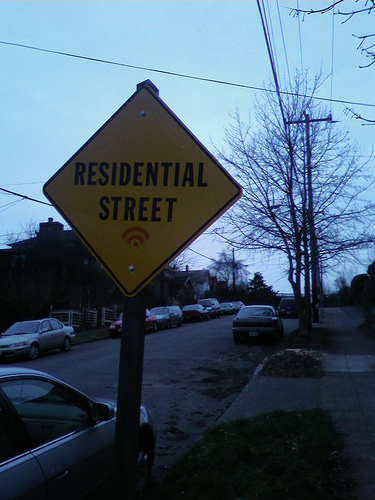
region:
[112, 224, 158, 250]
a few orange lines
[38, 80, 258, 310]
a bright yellow street sign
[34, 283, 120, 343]
a simple wood fence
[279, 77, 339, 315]
a wood telephone post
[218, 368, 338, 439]
a concrete drive way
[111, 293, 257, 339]
a row of parked cars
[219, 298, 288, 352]
a light colored sedan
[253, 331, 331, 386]
a patch of grass covered in leaves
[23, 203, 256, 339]
a row of houses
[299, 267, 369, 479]
a long cement sidewalk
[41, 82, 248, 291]
a yellow street sign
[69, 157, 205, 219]
black printed words RESIDENTIAL STREET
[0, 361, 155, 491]
a parked silver car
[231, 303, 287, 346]
a parked silver car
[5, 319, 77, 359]
a parked white car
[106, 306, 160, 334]
a parked red car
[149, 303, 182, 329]
a parked silver car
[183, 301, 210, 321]
a parked black car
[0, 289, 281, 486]
a paved city street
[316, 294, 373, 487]
a paved city sidewalk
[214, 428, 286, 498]
the grass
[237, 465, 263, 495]
the grass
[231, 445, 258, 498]
the grass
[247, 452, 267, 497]
the grass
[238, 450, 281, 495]
the grass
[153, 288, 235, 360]
plenty cars on street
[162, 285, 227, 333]
plenty cars on street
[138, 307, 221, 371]
plenty cars on street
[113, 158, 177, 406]
the sign is yellow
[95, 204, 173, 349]
the sign is yellow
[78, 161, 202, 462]
the sign is yellow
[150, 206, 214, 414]
the sign is yellow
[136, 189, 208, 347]
the sign is yellow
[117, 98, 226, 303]
the sign is yellow